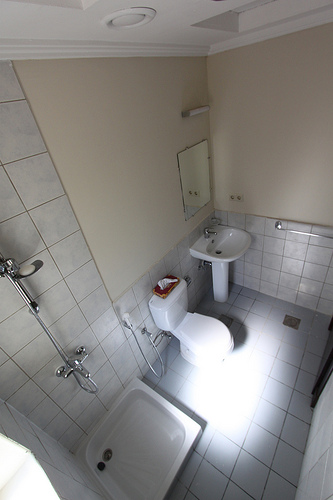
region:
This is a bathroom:
[10, 177, 311, 454]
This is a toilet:
[147, 275, 239, 372]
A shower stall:
[31, 315, 197, 493]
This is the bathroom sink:
[188, 222, 256, 301]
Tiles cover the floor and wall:
[258, 404, 328, 496]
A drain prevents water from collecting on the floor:
[281, 308, 308, 336]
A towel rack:
[271, 218, 330, 241]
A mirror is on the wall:
[172, 134, 217, 220]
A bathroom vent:
[99, 6, 162, 36]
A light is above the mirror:
[178, 100, 216, 160]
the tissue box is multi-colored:
[145, 274, 186, 302]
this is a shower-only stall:
[0, 241, 122, 499]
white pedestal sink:
[183, 226, 264, 315]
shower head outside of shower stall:
[116, 306, 173, 380]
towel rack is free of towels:
[273, 207, 332, 269]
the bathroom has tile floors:
[2, 199, 331, 499]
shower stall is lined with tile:
[0, 198, 129, 499]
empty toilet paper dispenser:
[179, 268, 198, 292]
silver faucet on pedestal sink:
[199, 220, 225, 244]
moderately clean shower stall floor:
[48, 391, 213, 499]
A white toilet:
[148, 275, 234, 369]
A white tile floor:
[139, 280, 332, 499]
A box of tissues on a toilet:
[153, 272, 179, 298]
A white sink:
[189, 220, 252, 302]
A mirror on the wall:
[176, 139, 212, 221]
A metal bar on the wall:
[276, 220, 332, 239]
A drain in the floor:
[282, 312, 301, 329]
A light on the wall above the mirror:
[182, 103, 210, 118]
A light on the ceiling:
[103, 6, 155, 32]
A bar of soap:
[18, 263, 35, 274]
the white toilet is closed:
[131, 271, 244, 371]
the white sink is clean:
[184, 215, 252, 263]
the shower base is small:
[77, 370, 214, 498]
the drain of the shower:
[92, 449, 118, 471]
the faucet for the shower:
[1, 256, 114, 402]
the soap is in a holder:
[16, 258, 40, 285]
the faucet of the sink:
[197, 226, 226, 243]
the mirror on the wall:
[157, 137, 227, 222]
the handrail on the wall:
[274, 217, 331, 251]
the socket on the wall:
[225, 194, 258, 211]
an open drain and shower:
[84, 375, 202, 499]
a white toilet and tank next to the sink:
[147, 274, 231, 367]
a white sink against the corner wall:
[188, 218, 248, 299]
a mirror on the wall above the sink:
[176, 139, 211, 220]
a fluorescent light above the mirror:
[180, 103, 210, 118]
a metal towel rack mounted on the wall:
[275, 221, 332, 240]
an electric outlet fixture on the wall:
[229, 192, 243, 201]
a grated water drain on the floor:
[282, 313, 301, 330]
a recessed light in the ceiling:
[103, 6, 155, 28]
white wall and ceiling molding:
[0, 40, 209, 59]